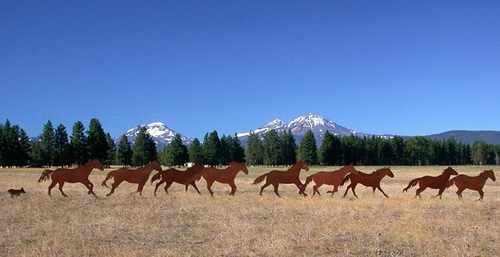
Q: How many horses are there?
A: Nine.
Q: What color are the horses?
A: Brown.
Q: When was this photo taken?
A: Day time.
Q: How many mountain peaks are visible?
A: Three.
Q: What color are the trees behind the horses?
A: Green.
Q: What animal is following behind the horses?
A: A dog.